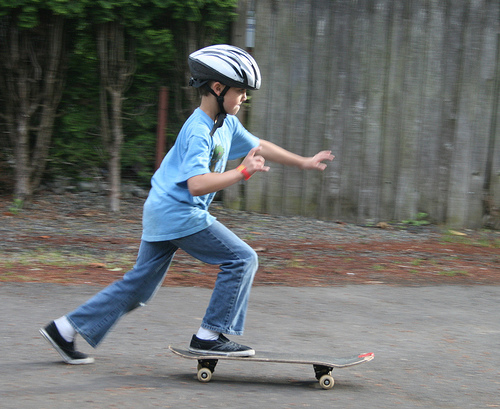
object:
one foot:
[188, 328, 257, 357]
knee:
[242, 246, 260, 275]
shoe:
[37, 321, 96, 364]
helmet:
[187, 44, 261, 90]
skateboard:
[167, 345, 374, 390]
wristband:
[236, 165, 252, 180]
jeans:
[64, 218, 260, 349]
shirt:
[141, 106, 269, 243]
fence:
[223, 0, 499, 224]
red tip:
[357, 351, 375, 359]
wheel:
[196, 368, 213, 384]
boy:
[34, 42, 335, 369]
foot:
[35, 315, 95, 366]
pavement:
[0, 283, 500, 408]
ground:
[0, 191, 500, 409]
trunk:
[109, 93, 125, 212]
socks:
[51, 316, 76, 343]